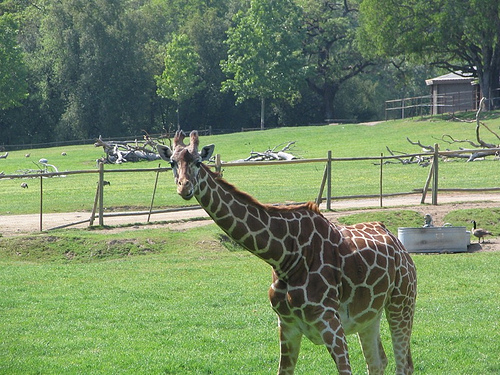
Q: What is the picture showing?
A: It is showing a field.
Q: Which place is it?
A: It is a field.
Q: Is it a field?
A: Yes, it is a field.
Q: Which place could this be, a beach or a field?
A: It is a field.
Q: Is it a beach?
A: No, it is a field.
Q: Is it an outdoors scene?
A: Yes, it is outdoors.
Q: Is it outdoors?
A: Yes, it is outdoors.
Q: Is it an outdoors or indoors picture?
A: It is outdoors.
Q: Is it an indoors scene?
A: No, it is outdoors.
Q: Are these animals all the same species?
A: No, there are both giraffes and birds.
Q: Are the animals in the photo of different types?
A: Yes, they are giraffes and birds.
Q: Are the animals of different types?
A: Yes, they are giraffes and birds.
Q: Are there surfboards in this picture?
A: No, there are no surfboards.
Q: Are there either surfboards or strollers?
A: No, there are no surfboards or strollers.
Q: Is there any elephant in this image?
A: No, there are no elephants.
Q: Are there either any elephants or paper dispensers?
A: No, there are no elephants or paper dispensers.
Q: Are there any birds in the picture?
A: Yes, there are birds.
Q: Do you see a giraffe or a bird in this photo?
A: Yes, there are birds.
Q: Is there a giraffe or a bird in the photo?
A: Yes, there are birds.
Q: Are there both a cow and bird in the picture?
A: No, there are birds but no cows.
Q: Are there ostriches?
A: No, there are no ostriches.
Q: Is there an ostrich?
A: No, there are no ostriches.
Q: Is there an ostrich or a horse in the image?
A: No, there are no ostriches or horses.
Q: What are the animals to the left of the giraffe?
A: The animals are birds.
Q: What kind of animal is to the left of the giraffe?
A: The animals are birds.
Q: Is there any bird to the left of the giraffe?
A: Yes, there are birds to the left of the giraffe.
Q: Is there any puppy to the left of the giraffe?
A: No, there are birds to the left of the giraffe.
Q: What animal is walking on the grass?
A: The birds are walking on the grass.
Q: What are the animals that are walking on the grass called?
A: The animals are birds.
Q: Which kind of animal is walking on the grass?
A: The animals are birds.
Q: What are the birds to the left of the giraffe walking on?
A: The birds are walking on the grass.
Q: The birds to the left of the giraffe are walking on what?
A: The birds are walking on the grass.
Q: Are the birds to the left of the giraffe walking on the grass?
A: Yes, the birds are walking on the grass.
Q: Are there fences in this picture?
A: Yes, there is a fence.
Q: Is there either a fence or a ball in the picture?
A: Yes, there is a fence.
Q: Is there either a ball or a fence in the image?
A: Yes, there is a fence.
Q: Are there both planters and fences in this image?
A: No, there is a fence but no planters.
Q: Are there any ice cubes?
A: No, there are no ice cubes.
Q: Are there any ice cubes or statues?
A: No, there are no ice cubes or statues.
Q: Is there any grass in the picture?
A: Yes, there is grass.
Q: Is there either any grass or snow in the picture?
A: Yes, there is grass.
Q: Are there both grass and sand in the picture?
A: No, there is grass but no sand.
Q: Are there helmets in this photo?
A: No, there are no helmets.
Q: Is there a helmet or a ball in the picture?
A: No, there are no helmets or balls.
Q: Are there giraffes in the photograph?
A: Yes, there is a giraffe.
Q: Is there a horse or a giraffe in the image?
A: Yes, there is a giraffe.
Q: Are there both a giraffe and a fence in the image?
A: Yes, there are both a giraffe and a fence.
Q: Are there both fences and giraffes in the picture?
A: Yes, there are both a giraffe and a fence.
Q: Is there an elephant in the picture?
A: No, there are no elephants.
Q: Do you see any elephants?
A: No, there are no elephants.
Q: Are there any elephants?
A: No, there are no elephants.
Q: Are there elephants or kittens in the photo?
A: No, there are no elephants or kittens.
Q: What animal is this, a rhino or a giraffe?
A: This is a giraffe.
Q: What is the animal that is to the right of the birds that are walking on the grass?
A: The animal is a giraffe.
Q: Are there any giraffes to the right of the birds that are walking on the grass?
A: Yes, there is a giraffe to the right of the birds.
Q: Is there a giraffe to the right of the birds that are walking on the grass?
A: Yes, there is a giraffe to the right of the birds.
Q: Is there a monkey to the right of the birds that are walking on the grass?
A: No, there is a giraffe to the right of the birds.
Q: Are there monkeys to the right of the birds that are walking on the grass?
A: No, there is a giraffe to the right of the birds.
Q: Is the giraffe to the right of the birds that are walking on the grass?
A: Yes, the giraffe is to the right of the birds.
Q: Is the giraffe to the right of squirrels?
A: No, the giraffe is to the right of the birds.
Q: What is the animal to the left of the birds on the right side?
A: The animal is a giraffe.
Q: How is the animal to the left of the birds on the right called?
A: The animal is a giraffe.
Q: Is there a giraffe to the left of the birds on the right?
A: Yes, there is a giraffe to the left of the birds.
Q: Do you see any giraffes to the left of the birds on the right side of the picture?
A: Yes, there is a giraffe to the left of the birds.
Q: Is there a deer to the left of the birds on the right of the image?
A: No, there is a giraffe to the left of the birds.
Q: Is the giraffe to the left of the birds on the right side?
A: Yes, the giraffe is to the left of the birds.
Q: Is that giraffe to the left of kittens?
A: No, the giraffe is to the left of the birds.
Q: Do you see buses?
A: No, there are no buses.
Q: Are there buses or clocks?
A: No, there are no buses or clocks.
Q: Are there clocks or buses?
A: No, there are no buses or clocks.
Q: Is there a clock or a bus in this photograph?
A: No, there are no buses or clocks.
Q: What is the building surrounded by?
A: The building is surrounded by the fence.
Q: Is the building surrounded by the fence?
A: Yes, the building is surrounded by the fence.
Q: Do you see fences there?
A: Yes, there is a fence.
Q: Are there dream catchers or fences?
A: Yes, there is a fence.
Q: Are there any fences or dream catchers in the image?
A: Yes, there is a fence.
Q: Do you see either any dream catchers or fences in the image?
A: Yes, there is a fence.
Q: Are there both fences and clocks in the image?
A: No, there is a fence but no clocks.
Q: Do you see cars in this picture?
A: No, there are no cars.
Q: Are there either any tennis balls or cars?
A: No, there are no cars or tennis balls.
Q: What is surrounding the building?
A: The fence is surrounding the building.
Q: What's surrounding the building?
A: The fence is surrounding the building.